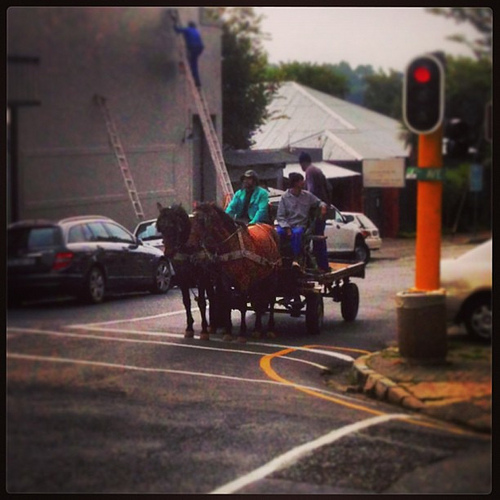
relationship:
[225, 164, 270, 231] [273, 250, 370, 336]
man on cart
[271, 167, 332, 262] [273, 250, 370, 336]
man on cart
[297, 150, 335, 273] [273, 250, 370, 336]
man on cart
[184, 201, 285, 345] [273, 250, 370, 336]
horse pulling cart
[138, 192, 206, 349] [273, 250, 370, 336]
horse pulling cart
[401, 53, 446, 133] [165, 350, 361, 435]
light on corner street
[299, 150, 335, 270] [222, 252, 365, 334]
man standing on cart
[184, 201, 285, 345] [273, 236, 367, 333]
horse pulling carriage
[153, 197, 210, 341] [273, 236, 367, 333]
horse pulling carriage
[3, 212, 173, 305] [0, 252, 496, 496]
car parked street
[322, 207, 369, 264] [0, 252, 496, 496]
jeep parked street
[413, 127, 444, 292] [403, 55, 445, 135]
pole on pole light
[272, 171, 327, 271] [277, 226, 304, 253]
man wearing blue pants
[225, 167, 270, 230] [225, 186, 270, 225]
man wearing coat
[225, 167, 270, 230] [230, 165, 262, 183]
man wearing hat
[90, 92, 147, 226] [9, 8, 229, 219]
ladder against building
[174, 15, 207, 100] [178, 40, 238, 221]
man standing on a ladder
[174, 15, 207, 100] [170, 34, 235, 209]
man climbing ladder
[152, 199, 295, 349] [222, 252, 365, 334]
horse pulling a cart